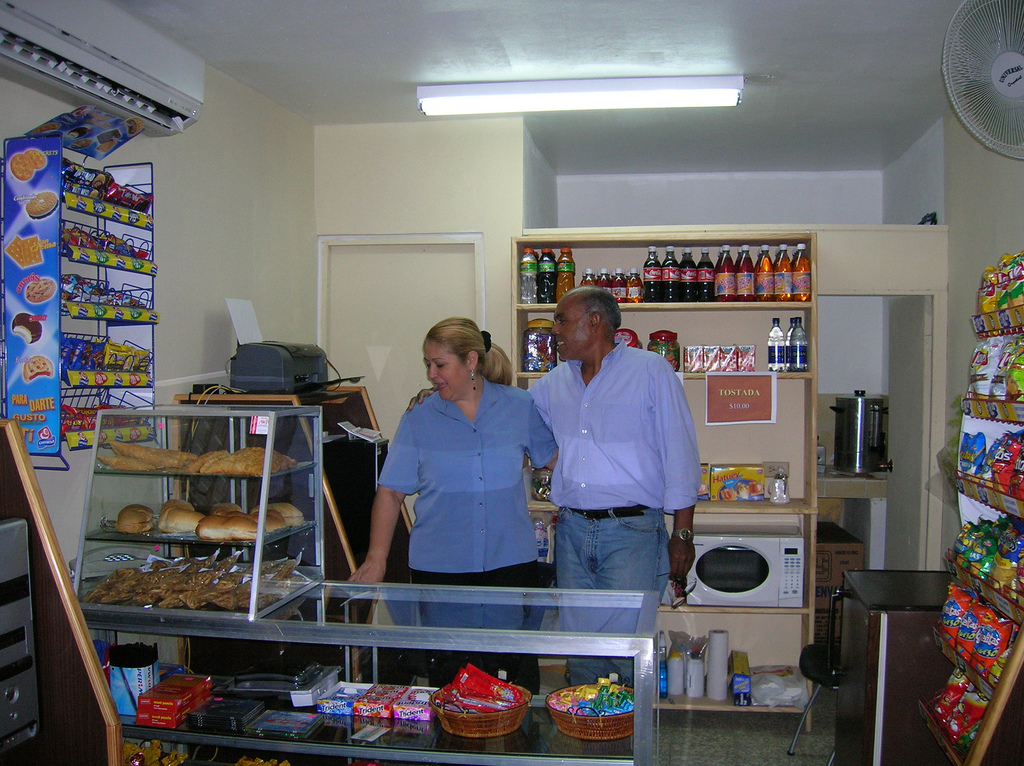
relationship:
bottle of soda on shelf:
[761, 292, 781, 347] [674, 265, 787, 520]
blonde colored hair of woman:
[443, 308, 496, 373] [357, 304, 554, 631]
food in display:
[79, 402, 318, 616] [108, 496, 156, 602]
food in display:
[79, 402, 318, 616] [212, 388, 306, 603]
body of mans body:
[417, 437, 519, 493] [562, 356, 694, 560]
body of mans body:
[417, 437, 519, 493] [637, 373, 735, 572]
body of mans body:
[417, 437, 519, 493] [663, 470, 700, 680]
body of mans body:
[417, 437, 519, 493] [618, 509, 657, 581]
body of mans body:
[417, 437, 519, 493] [562, 531, 593, 646]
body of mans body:
[417, 437, 519, 493] [545, 460, 647, 620]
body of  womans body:
[417, 437, 519, 493] [423, 338, 460, 432]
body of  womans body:
[417, 437, 519, 493] [350, 526, 420, 661]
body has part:
[417, 437, 519, 494] [447, 532, 448, 550]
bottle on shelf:
[761, 292, 781, 347] [646, 286, 806, 328]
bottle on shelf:
[761, 292, 781, 347] [669, 301, 810, 340]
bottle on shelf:
[761, 292, 781, 347] [693, 283, 787, 310]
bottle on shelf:
[761, 292, 781, 347] [658, 296, 808, 303]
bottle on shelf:
[761, 292, 781, 347] [678, 299, 802, 308]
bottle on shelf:
[689, 275, 750, 278] [660, 305, 844, 310]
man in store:
[347, 314, 557, 700] [0, 3, 990, 757]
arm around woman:
[391, 368, 571, 444] [313, 279, 555, 623]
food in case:
[110, 422, 286, 623] [69, 357, 359, 705]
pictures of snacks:
[4, 128, 59, 457] [13, 148, 59, 470]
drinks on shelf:
[512, 232, 841, 330] [519, 288, 826, 325]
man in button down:
[506, 258, 723, 654] [517, 335, 712, 524]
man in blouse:
[347, 314, 557, 700] [372, 376, 574, 573]